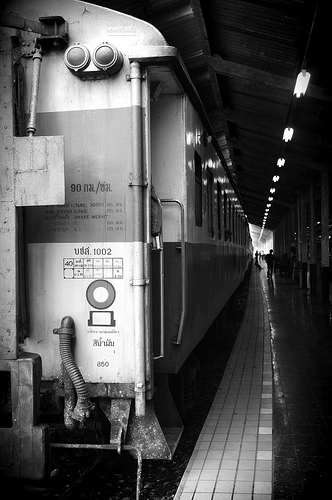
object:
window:
[205, 161, 216, 238]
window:
[216, 179, 224, 239]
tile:
[220, 459, 240, 472]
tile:
[252, 480, 274, 493]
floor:
[73, 257, 332, 499]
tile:
[259, 407, 273, 416]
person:
[264, 249, 276, 283]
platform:
[141, 254, 332, 499]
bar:
[158, 195, 186, 346]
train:
[0, 2, 253, 498]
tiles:
[185, 467, 201, 480]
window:
[193, 146, 205, 230]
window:
[223, 191, 229, 246]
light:
[90, 40, 124, 77]